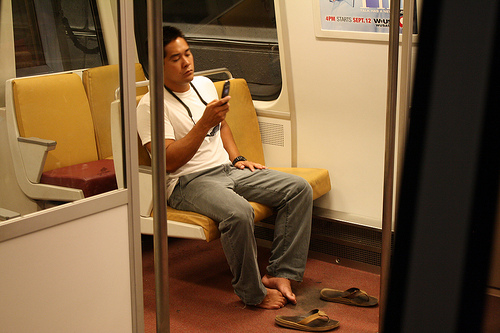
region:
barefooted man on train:
[229, 227, 316, 309]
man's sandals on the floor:
[282, 280, 379, 331]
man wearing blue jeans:
[170, 145, 317, 307]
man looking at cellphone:
[204, 73, 238, 135]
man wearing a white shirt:
[126, 67, 245, 182]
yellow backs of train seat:
[212, 75, 333, 186]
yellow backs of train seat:
[124, 86, 217, 233]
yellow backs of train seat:
[83, 63, 160, 160]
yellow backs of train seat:
[15, 75, 102, 171]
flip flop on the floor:
[308, 278, 375, 309]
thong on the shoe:
[312, 310, 337, 327]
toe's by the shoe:
[261, 289, 302, 329]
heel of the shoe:
[263, 313, 298, 330]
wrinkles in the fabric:
[233, 171, 289, 199]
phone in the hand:
[216, 75, 236, 115]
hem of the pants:
[252, 272, 313, 284]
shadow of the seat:
[163, 251, 222, 299]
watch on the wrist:
[226, 145, 251, 170]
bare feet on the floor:
[231, 265, 320, 325]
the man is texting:
[139, 31, 250, 158]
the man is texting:
[147, 31, 242, 153]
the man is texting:
[139, 36, 244, 162]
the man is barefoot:
[208, 257, 310, 322]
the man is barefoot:
[239, 264, 301, 324]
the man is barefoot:
[231, 259, 332, 327]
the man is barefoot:
[232, 254, 319, 331]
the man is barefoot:
[220, 251, 307, 316]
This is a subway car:
[10, 7, 480, 311]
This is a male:
[144, 26, 331, 296]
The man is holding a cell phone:
[203, 64, 238, 126]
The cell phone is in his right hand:
[189, 67, 245, 141]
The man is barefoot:
[240, 248, 305, 312]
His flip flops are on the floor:
[265, 259, 378, 331]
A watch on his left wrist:
[230, 153, 250, 168]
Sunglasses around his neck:
[160, 65, 233, 140]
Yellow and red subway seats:
[21, 60, 146, 191]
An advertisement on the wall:
[310, 6, 402, 50]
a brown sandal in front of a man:
[272, 303, 344, 330]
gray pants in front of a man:
[169, 162, 315, 309]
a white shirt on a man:
[142, 73, 225, 199]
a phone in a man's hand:
[220, 75, 232, 107]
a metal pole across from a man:
[144, 1, 171, 331]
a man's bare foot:
[260, 273, 298, 303]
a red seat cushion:
[42, 155, 122, 197]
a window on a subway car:
[125, 0, 288, 99]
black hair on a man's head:
[145, 24, 188, 67]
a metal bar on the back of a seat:
[116, 61, 241, 99]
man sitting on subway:
[138, 20, 320, 317]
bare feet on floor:
[253, 258, 319, 320]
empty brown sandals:
[267, 277, 378, 332]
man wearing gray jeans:
[138, 26, 324, 299]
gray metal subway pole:
[143, 2, 185, 329]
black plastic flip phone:
[218, 75, 238, 125]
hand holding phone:
[201, 77, 238, 132]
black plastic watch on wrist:
[231, 148, 253, 169]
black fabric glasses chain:
[165, 78, 217, 121]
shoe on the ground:
[309, 269, 379, 319]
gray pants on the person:
[158, 151, 326, 297]